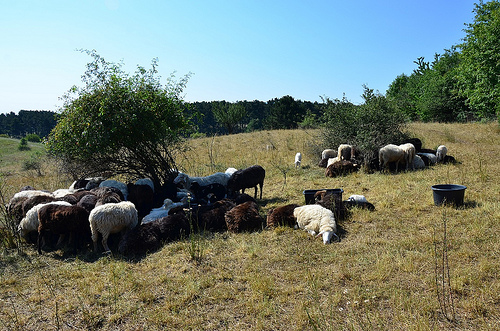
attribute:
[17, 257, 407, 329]
grass — green, brown, short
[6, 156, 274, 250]
herd — clustered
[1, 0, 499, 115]
clouds — white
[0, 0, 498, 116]
sky — blue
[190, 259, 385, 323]
grass — green, short, brown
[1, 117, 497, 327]
grass — short, brown, green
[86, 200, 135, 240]
wool — long, white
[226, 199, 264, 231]
sheep — brown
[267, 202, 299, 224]
sheep — brown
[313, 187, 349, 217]
sheep — brown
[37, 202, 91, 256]
sheep — brown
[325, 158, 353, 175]
sheep — brown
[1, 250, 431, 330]
grass — short, brown, green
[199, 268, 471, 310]
grass — brown, short, green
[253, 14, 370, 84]
sky — blue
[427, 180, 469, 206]
black bucket — round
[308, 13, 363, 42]
sky — blue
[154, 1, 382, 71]
sky — clear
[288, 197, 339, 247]
sheep — sleeping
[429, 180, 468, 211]
bucket — black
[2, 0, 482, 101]
sky — blue